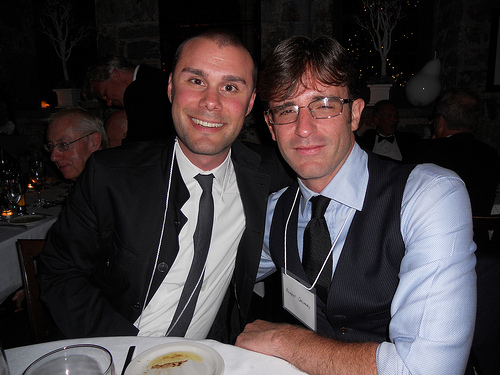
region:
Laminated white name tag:
[271, 261, 335, 336]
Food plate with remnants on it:
[122, 337, 224, 374]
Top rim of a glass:
[21, 331, 117, 373]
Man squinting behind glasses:
[267, 92, 346, 127]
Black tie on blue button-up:
[292, 188, 349, 298]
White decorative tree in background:
[358, 0, 402, 79]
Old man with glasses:
[37, 105, 112, 186]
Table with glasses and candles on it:
[0, 161, 59, 236]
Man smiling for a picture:
[158, 30, 263, 162]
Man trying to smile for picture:
[258, 31, 368, 186]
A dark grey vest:
[238, 150, 469, 374]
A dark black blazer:
[32, 115, 300, 374]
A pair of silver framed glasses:
[256, 88, 374, 132]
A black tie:
[162, 166, 217, 351]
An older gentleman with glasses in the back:
[37, 106, 129, 198]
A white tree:
[350, 1, 422, 118]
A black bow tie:
[372, 129, 404, 148]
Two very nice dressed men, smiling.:
[39, 23, 481, 370]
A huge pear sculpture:
[385, 35, 450, 115]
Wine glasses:
[2, 161, 53, 216]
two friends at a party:
[66, 40, 410, 373]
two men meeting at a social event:
[120, 5, 425, 370]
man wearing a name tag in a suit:
[257, 38, 431, 373]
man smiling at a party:
[81, 13, 266, 357]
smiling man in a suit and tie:
[97, 20, 273, 344]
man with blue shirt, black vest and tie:
[256, 3, 441, 373]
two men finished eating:
[58, 23, 468, 373]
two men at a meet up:
[85, 11, 463, 373]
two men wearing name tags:
[128, 13, 398, 363]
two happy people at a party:
[84, 15, 467, 373]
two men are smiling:
[154, 38, 424, 249]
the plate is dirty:
[114, 333, 174, 373]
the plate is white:
[99, 330, 244, 369]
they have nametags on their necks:
[133, 181, 390, 363]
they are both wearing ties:
[146, 150, 439, 345]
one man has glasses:
[154, 52, 427, 244]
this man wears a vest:
[271, 83, 485, 300]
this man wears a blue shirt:
[273, 75, 488, 283]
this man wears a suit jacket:
[93, 72, 238, 302]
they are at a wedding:
[56, 22, 475, 255]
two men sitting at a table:
[136, 37, 443, 351]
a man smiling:
[161, 32, 266, 163]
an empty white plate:
[133, 330, 245, 372]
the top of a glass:
[35, 340, 115, 374]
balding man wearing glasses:
[41, 109, 112, 179]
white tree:
[361, 4, 417, 94]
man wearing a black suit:
[89, 52, 169, 128]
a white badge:
[282, 175, 345, 326]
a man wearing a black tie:
[170, 34, 247, 334]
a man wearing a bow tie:
[373, 95, 408, 159]